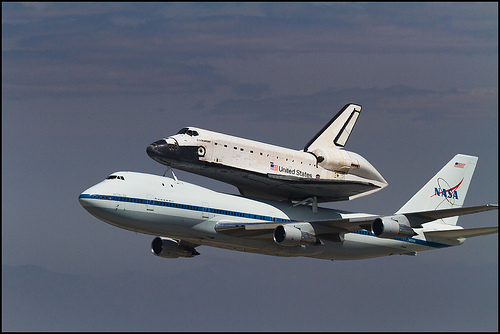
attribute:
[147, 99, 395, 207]
space shuttle — rides piggyback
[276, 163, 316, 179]
united states — written on the side 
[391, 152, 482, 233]
tail — Nasa written on, jet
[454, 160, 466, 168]
flag — American